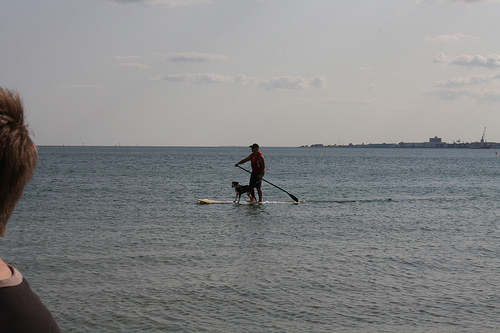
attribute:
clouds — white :
[146, 50, 338, 92]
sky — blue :
[27, 12, 491, 137]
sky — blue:
[246, 30, 396, 92]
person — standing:
[90, 59, 457, 316]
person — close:
[221, 122, 287, 223]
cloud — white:
[167, 50, 222, 65]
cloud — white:
[263, 73, 307, 95]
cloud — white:
[153, 68, 220, 93]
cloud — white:
[438, 50, 498, 69]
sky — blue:
[29, 1, 496, 139]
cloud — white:
[415, 28, 498, 108]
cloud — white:
[102, 27, 333, 91]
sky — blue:
[6, 24, 498, 149]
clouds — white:
[119, 44, 359, 104]